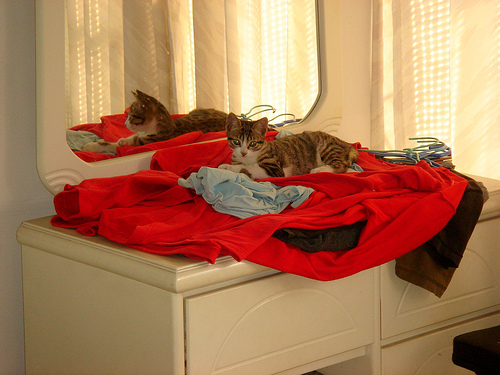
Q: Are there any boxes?
A: No, there are no boxes.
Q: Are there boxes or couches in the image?
A: No, there are no boxes or couches.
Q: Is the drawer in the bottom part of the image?
A: Yes, the drawer is in the bottom of the image.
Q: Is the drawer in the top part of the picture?
A: No, the drawer is in the bottom of the image.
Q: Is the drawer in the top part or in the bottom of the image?
A: The drawer is in the bottom of the image.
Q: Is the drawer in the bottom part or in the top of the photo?
A: The drawer is in the bottom of the image.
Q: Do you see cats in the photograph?
A: Yes, there is a cat.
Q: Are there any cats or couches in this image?
A: Yes, there is a cat.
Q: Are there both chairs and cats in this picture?
A: No, there is a cat but no chairs.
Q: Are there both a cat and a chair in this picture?
A: No, there is a cat but no chairs.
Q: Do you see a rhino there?
A: No, there are no rhinos.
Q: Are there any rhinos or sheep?
A: No, there are no rhinos or sheep.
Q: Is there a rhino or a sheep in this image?
A: No, there are no rhinos or sheep.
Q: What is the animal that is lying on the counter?
A: The animal is a cat.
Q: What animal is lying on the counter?
A: The animal is a cat.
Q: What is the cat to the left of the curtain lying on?
A: The cat is lying on the counter.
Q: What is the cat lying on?
A: The cat is lying on the counter.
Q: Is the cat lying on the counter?
A: Yes, the cat is lying on the counter.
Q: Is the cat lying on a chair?
A: No, the cat is lying on the counter.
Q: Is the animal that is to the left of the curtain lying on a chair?
A: No, the cat is lying on the counter.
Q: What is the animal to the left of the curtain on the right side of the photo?
A: The animal is a cat.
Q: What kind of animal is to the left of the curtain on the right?
A: The animal is a cat.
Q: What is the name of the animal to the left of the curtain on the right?
A: The animal is a cat.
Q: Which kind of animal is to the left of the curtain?
A: The animal is a cat.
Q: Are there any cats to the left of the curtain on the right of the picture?
A: Yes, there is a cat to the left of the curtain.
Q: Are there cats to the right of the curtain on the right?
A: No, the cat is to the left of the curtain.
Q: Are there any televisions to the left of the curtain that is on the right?
A: No, there is a cat to the left of the curtain.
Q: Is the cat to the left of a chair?
A: No, the cat is to the left of the curtain.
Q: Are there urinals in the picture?
A: No, there are no urinals.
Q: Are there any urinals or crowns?
A: No, there are no urinals or crowns.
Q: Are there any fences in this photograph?
A: No, there are no fences.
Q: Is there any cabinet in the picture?
A: Yes, there is a cabinet.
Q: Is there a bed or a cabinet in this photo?
A: Yes, there is a cabinet.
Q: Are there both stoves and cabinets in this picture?
A: No, there is a cabinet but no stoves.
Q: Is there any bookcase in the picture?
A: No, there are no bookcases.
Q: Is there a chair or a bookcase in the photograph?
A: No, there are no bookcases or chairs.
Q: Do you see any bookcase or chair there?
A: No, there are no bookcases or chairs.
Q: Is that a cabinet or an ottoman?
A: That is a cabinet.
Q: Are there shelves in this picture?
A: No, there are no shelves.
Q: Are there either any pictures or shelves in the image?
A: No, there are no shelves or pictures.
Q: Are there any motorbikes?
A: No, there are no motorbikes.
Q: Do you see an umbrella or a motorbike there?
A: No, there are no motorcycles or umbrellas.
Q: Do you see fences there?
A: No, there are no fences.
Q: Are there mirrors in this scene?
A: Yes, there is a mirror.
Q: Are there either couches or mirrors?
A: Yes, there is a mirror.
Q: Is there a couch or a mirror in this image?
A: Yes, there is a mirror.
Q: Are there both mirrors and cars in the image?
A: No, there is a mirror but no cars.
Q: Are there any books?
A: No, there are no books.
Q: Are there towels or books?
A: No, there are no books or towels.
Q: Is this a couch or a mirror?
A: This is a mirror.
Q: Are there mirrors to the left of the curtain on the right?
A: Yes, there is a mirror to the left of the curtain.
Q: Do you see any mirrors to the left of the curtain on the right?
A: Yes, there is a mirror to the left of the curtain.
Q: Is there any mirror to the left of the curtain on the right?
A: Yes, there is a mirror to the left of the curtain.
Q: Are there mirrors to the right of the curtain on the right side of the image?
A: No, the mirror is to the left of the curtain.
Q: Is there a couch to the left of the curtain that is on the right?
A: No, there is a mirror to the left of the curtain.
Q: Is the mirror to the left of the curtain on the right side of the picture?
A: Yes, the mirror is to the left of the curtain.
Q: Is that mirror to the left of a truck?
A: No, the mirror is to the left of the curtain.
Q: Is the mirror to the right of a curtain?
A: No, the mirror is to the left of a curtain.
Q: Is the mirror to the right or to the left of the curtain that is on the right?
A: The mirror is to the left of the curtain.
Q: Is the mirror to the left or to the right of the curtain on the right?
A: The mirror is to the left of the curtain.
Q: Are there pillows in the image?
A: No, there are no pillows.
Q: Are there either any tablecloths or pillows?
A: No, there are no pillows or tablecloths.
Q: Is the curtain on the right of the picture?
A: Yes, the curtain is on the right of the image.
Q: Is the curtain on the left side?
A: No, the curtain is on the right of the image.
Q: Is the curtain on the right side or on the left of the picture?
A: The curtain is on the right of the image.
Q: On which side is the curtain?
A: The curtain is on the right of the image.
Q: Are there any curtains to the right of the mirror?
A: Yes, there is a curtain to the right of the mirror.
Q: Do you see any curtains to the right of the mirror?
A: Yes, there is a curtain to the right of the mirror.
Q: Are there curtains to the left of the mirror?
A: No, the curtain is to the right of the mirror.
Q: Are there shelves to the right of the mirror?
A: No, there is a curtain to the right of the mirror.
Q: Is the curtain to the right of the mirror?
A: Yes, the curtain is to the right of the mirror.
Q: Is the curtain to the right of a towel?
A: No, the curtain is to the right of the mirror.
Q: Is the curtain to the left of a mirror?
A: No, the curtain is to the right of a mirror.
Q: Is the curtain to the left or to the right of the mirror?
A: The curtain is to the right of the mirror.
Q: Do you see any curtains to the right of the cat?
A: Yes, there is a curtain to the right of the cat.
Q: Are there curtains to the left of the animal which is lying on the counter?
A: No, the curtain is to the right of the cat.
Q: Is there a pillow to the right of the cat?
A: No, there is a curtain to the right of the cat.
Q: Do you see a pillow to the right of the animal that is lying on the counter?
A: No, there is a curtain to the right of the cat.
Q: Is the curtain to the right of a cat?
A: Yes, the curtain is to the right of a cat.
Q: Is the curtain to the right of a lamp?
A: No, the curtain is to the right of a cat.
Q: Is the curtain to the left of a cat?
A: No, the curtain is to the right of a cat.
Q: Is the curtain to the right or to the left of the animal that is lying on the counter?
A: The curtain is to the right of the cat.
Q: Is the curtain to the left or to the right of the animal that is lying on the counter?
A: The curtain is to the right of the cat.